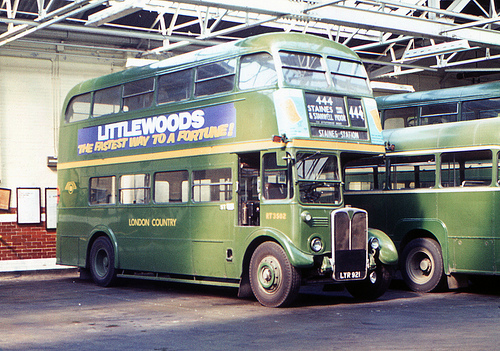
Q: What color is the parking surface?
A: Grey.